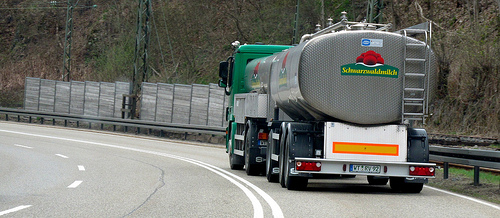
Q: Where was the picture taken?
A: It was taken at the road.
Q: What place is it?
A: It is a road.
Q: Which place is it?
A: It is a road.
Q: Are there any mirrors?
A: Yes, there is a mirror.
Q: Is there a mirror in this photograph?
A: Yes, there is a mirror.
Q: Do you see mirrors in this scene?
A: Yes, there is a mirror.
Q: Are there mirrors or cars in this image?
A: Yes, there is a mirror.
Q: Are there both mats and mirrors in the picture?
A: No, there is a mirror but no mats.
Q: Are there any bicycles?
A: No, there are no bicycles.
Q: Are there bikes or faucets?
A: No, there are no bikes or faucets.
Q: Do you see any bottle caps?
A: No, there are no bottle caps.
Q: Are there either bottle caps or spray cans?
A: No, there are no bottle caps or spray cans.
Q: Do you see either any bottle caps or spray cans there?
A: No, there are no bottle caps or spray cans.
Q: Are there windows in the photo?
A: Yes, there is a window.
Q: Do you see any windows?
A: Yes, there is a window.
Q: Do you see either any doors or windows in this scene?
A: Yes, there is a window.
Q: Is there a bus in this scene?
A: No, there are no buses.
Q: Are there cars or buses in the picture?
A: No, there are no buses or cars.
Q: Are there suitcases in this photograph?
A: No, there are no suitcases.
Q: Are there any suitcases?
A: No, there are no suitcases.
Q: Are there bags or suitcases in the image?
A: No, there are no suitcases or bags.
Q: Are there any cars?
A: No, there are no cars.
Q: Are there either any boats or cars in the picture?
A: No, there are no cars or boats.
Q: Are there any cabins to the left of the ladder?
A: Yes, there is a cabin to the left of the ladder.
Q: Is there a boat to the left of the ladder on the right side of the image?
A: No, there is a cabin to the left of the ladder.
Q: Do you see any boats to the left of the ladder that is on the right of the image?
A: No, there is a cabin to the left of the ladder.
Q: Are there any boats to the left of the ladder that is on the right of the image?
A: No, there is a cabin to the left of the ladder.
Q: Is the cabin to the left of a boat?
A: No, the cabin is to the left of the ladder.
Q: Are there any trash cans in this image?
A: No, there are no trash cans.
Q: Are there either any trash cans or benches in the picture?
A: No, there are no trash cans or benches.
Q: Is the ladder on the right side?
A: Yes, the ladder is on the right of the image.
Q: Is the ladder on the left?
A: No, the ladder is on the right of the image.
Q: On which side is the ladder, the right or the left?
A: The ladder is on the right of the image.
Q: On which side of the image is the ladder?
A: The ladder is on the right of the image.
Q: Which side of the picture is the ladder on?
A: The ladder is on the right of the image.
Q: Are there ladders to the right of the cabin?
A: Yes, there is a ladder to the right of the cabin.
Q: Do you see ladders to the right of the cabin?
A: Yes, there is a ladder to the right of the cabin.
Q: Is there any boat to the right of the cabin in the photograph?
A: No, there is a ladder to the right of the cabin.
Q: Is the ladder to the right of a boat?
A: No, the ladder is to the right of the cabin.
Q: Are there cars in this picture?
A: No, there are no cars.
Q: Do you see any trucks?
A: Yes, there is a truck.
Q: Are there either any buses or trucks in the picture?
A: Yes, there is a truck.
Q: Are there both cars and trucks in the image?
A: No, there is a truck but no cars.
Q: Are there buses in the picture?
A: No, there are no buses.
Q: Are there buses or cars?
A: No, there are no buses or cars.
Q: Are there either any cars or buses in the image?
A: No, there are no buses or cars.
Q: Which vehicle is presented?
A: The vehicle is a truck.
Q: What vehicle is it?
A: The vehicle is a truck.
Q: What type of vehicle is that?
A: This is a truck.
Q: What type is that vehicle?
A: This is a truck.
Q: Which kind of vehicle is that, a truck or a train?
A: This is a truck.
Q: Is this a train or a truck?
A: This is a truck.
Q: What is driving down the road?
A: The truck is driving down the road.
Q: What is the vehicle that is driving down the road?
A: The vehicle is a truck.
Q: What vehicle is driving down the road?
A: The vehicle is a truck.